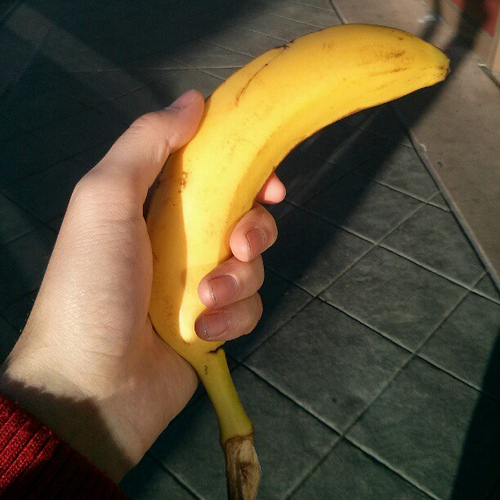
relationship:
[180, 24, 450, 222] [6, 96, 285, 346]
banana in hand